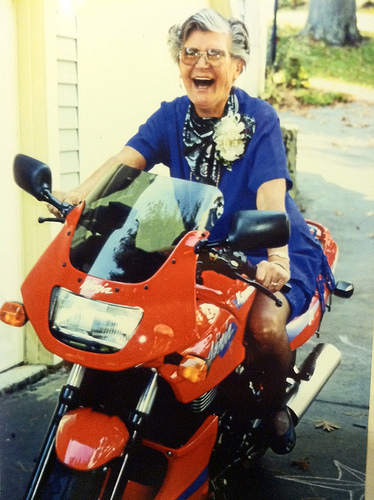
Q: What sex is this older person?
A: Female.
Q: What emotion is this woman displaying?
A: Happiness.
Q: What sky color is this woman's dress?
A: Blue.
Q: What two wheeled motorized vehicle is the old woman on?
A: Motorcycle.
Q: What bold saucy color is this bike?
A: Red.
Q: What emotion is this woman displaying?
A: Happiness.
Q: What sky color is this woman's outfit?
A: Blue.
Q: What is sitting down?
A: The woman.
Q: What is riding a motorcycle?
A: The woman.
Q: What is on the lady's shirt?
A: The white flower.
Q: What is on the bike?
A: The headlight.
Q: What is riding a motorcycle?
A: The woman.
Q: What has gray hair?
A: The woman.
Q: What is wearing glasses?
A: The woman.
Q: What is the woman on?
A: Motorcycle.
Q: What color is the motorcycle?
A: Red.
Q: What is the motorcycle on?
A: Concrete.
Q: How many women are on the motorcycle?
A: One.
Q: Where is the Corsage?
A: Woman's dress.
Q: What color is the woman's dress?
A: Blue.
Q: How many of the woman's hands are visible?
A: Two.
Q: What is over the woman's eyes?
A: Glasses.